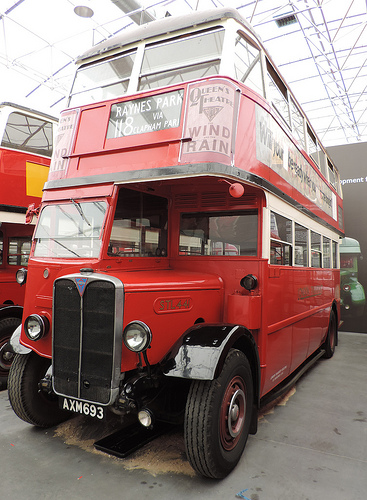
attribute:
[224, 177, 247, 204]
mirror — rear side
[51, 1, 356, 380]
bus — red, double decker, gray, white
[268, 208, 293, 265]
window — along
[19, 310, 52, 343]
headlight — circular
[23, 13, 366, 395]
bus — red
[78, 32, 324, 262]
double decker — red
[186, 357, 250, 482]
wheel — large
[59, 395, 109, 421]
license plate — black, white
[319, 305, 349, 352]
tire — black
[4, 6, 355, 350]
bus — red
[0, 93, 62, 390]
buses — double decker, parked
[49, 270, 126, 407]
grill — double decker, black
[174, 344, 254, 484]
tire — black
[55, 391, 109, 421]
license plate — black, white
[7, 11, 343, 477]
bus — red, double decker, large, parked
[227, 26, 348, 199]
windows — upper section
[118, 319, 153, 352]
headlight — shiny, round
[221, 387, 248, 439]
hubcap — grey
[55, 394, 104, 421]
license — white, black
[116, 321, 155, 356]
headlight — circular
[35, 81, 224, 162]
sign — black, white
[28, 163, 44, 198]
paint — yellow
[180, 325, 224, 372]
fender — black, shiny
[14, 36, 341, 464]
bus — double decker